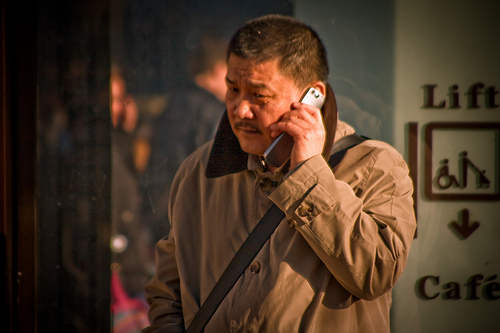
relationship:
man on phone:
[146, 15, 420, 331] [265, 86, 326, 169]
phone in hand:
[265, 86, 326, 169] [270, 102, 327, 169]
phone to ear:
[265, 86, 326, 169] [312, 80, 324, 94]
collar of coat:
[203, 110, 247, 180] [144, 84, 417, 332]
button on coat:
[249, 259, 261, 275] [144, 84, 417, 332]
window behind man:
[37, 2, 393, 332] [146, 15, 420, 331]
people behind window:
[110, 37, 227, 332] [37, 2, 393, 332]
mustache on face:
[231, 122, 261, 133] [224, 56, 301, 157]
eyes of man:
[227, 82, 271, 101] [146, 15, 420, 331]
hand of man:
[270, 102, 327, 169] [146, 15, 420, 331]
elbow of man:
[341, 224, 403, 302] [146, 15, 420, 331]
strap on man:
[189, 132, 363, 330] [146, 15, 420, 331]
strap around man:
[189, 132, 363, 330] [146, 15, 420, 331]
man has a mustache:
[146, 15, 420, 331] [231, 122, 261, 133]